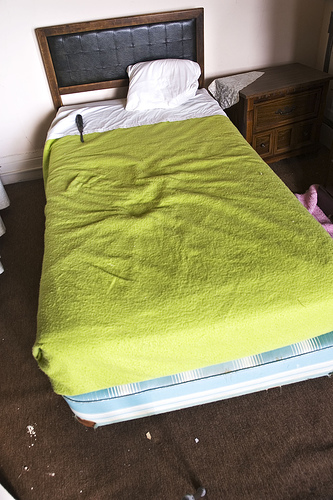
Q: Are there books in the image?
A: No, there are no books.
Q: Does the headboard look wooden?
A: Yes, the headboard is wooden.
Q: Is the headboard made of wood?
A: Yes, the headboard is made of wood.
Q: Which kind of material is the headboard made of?
A: The headboard is made of wood.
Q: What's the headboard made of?
A: The headboard is made of wood.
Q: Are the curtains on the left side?
A: Yes, the curtains are on the left of the image.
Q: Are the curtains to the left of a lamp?
A: No, the curtains are to the left of the bed.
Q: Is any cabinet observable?
A: Yes, there is a cabinet.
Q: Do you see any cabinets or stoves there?
A: Yes, there is a cabinet.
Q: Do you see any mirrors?
A: No, there are no mirrors.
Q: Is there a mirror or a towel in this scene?
A: No, there are no mirrors or towels.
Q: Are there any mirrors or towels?
A: No, there are no mirrors or towels.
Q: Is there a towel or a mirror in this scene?
A: No, there are no mirrors or towels.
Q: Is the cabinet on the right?
A: Yes, the cabinet is on the right of the image.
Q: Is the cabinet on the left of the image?
A: No, the cabinet is on the right of the image.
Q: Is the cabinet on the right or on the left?
A: The cabinet is on the right of the image.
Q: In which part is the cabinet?
A: The cabinet is on the right of the image.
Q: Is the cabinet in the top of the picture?
A: Yes, the cabinet is in the top of the image.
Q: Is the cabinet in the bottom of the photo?
A: No, the cabinet is in the top of the image.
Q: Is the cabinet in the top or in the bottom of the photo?
A: The cabinet is in the top of the image.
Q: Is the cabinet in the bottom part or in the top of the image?
A: The cabinet is in the top of the image.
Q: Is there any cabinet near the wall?
A: Yes, there is a cabinet near the wall.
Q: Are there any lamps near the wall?
A: No, there is a cabinet near the wall.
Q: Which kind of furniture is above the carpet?
A: The piece of furniture is a cabinet.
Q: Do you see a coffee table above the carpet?
A: No, there is a cabinet above the carpet.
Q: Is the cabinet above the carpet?
A: Yes, the cabinet is above the carpet.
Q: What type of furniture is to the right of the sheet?
A: The piece of furniture is a cabinet.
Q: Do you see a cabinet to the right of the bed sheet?
A: Yes, there is a cabinet to the right of the bed sheet.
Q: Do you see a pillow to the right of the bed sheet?
A: No, there is a cabinet to the right of the bed sheet.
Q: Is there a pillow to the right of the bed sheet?
A: No, there is a cabinet to the right of the bed sheet.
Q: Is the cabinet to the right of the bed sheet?
A: Yes, the cabinet is to the right of the bed sheet.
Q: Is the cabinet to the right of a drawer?
A: No, the cabinet is to the right of the bed sheet.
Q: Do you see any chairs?
A: No, there are no chairs.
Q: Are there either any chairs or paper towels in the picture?
A: No, there are no chairs or paper towels.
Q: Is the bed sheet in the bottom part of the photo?
A: No, the bed sheet is in the top of the image.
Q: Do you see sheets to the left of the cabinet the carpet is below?
A: Yes, there is a sheet to the left of the cabinet.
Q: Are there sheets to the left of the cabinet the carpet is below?
A: Yes, there is a sheet to the left of the cabinet.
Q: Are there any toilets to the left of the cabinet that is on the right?
A: No, there is a sheet to the left of the cabinet.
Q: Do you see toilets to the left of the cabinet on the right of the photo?
A: No, there is a sheet to the left of the cabinet.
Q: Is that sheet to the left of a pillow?
A: No, the sheet is to the left of the cabinet.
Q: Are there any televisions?
A: No, there are no televisions.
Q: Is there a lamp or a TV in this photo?
A: No, there are no televisions or lamps.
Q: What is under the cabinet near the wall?
A: The carpet is under the cabinet.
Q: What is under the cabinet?
A: The carpet is under the cabinet.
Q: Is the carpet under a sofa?
A: No, the carpet is under a cabinet.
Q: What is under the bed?
A: The carpet is under the bed.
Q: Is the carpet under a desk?
A: No, the carpet is under the bed.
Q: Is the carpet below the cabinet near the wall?
A: Yes, the carpet is below the cabinet.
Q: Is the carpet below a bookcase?
A: No, the carpet is below the cabinet.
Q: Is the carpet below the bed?
A: Yes, the carpet is below the bed.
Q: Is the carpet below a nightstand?
A: No, the carpet is below the bed.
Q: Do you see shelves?
A: No, there are no shelves.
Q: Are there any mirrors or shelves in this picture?
A: No, there are no shelves or mirrors.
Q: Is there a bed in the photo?
A: Yes, there is a bed.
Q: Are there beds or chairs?
A: Yes, there is a bed.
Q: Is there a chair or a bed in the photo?
A: Yes, there is a bed.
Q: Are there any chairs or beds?
A: Yes, there is a bed.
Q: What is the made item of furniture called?
A: The piece of furniture is a bed.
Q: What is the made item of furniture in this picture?
A: The piece of furniture is a bed.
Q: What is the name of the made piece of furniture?
A: The piece of furniture is a bed.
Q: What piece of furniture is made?
A: The piece of furniture is a bed.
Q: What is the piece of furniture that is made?
A: The piece of furniture is a bed.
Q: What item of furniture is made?
A: The piece of furniture is a bed.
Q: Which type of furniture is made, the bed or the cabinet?
A: The bed is made.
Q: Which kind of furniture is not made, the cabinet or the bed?
A: The cabinet is not made.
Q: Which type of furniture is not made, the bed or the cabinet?
A: The cabinet is not made.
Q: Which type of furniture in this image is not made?
A: The furniture is a cabinet.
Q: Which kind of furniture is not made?
A: The furniture is a cabinet.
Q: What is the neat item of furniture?
A: The piece of furniture is a bed.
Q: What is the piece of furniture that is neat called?
A: The piece of furniture is a bed.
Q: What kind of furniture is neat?
A: The furniture is a bed.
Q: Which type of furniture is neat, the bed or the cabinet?
A: The bed is neat.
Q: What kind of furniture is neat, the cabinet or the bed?
A: The bed is neat.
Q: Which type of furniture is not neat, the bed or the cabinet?
A: The cabinet is not neat.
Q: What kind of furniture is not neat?
A: The furniture is a cabinet.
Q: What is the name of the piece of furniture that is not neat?
A: The piece of furniture is a cabinet.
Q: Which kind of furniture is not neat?
A: The furniture is a cabinet.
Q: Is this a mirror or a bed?
A: This is a bed.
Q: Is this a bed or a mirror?
A: This is a bed.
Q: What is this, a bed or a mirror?
A: This is a bed.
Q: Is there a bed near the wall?
A: Yes, there is a bed near the wall.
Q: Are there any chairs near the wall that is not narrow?
A: No, there is a bed near the wall.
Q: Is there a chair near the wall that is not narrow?
A: No, there is a bed near the wall.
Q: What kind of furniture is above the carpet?
A: The piece of furniture is a bed.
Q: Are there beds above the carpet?
A: Yes, there is a bed above the carpet.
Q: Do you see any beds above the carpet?
A: Yes, there is a bed above the carpet.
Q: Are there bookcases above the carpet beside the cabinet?
A: No, there is a bed above the carpet.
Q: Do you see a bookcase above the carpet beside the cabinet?
A: No, there is a bed above the carpet.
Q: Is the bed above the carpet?
A: Yes, the bed is above the carpet.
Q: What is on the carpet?
A: The bed is on the carpet.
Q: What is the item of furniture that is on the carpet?
A: The piece of furniture is a bed.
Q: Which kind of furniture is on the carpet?
A: The piece of furniture is a bed.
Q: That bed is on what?
A: The bed is on the carpet.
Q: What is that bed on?
A: The bed is on the carpet.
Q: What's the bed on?
A: The bed is on the carpet.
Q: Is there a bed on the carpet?
A: Yes, there is a bed on the carpet.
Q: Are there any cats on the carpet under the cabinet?
A: No, there is a bed on the carpet.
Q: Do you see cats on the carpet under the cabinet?
A: No, there is a bed on the carpet.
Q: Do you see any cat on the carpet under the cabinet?
A: No, there is a bed on the carpet.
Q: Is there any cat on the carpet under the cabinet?
A: No, there is a bed on the carpet.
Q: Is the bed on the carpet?
A: Yes, the bed is on the carpet.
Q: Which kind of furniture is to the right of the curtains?
A: The piece of furniture is a bed.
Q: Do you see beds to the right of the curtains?
A: Yes, there is a bed to the right of the curtains.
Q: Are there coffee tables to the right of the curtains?
A: No, there is a bed to the right of the curtains.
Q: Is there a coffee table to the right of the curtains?
A: No, there is a bed to the right of the curtains.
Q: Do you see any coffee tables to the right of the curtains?
A: No, there is a bed to the right of the curtains.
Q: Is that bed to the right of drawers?
A: No, the bed is to the right of the curtains.